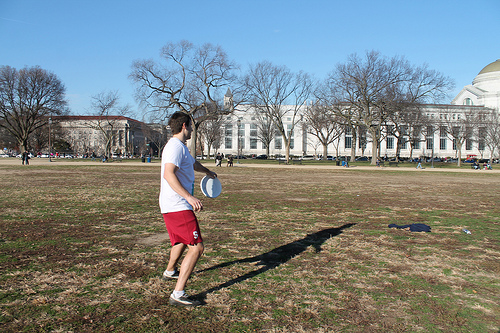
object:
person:
[157, 110, 219, 307]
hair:
[167, 109, 194, 134]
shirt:
[157, 136, 196, 214]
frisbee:
[200, 173, 224, 198]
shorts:
[160, 208, 204, 246]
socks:
[171, 289, 186, 298]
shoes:
[166, 291, 206, 306]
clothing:
[387, 222, 432, 233]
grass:
[50, 157, 499, 170]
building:
[200, 86, 500, 160]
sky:
[0, 0, 499, 125]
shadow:
[185, 221, 358, 306]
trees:
[308, 48, 456, 165]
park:
[1, 0, 500, 333]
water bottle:
[456, 225, 475, 236]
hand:
[204, 169, 219, 180]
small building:
[0, 115, 153, 161]